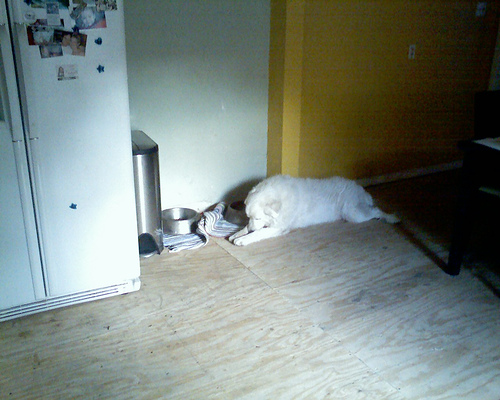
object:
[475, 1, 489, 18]
light switch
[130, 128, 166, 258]
trash can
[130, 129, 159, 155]
lid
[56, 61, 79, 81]
magnet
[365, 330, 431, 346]
post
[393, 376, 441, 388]
post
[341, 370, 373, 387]
post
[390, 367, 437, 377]
post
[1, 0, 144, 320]
refrigerator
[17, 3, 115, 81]
pictures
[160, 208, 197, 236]
bowl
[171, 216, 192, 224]
food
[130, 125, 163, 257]
can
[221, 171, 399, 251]
dog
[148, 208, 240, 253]
rug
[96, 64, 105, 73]
magnet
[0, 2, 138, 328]
fridge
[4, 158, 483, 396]
floor